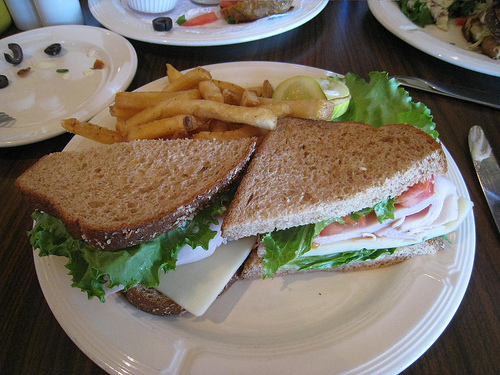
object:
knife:
[468, 123, 499, 232]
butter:
[468, 125, 488, 163]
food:
[14, 63, 475, 318]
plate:
[31, 61, 478, 374]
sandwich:
[219, 117, 474, 283]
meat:
[302, 175, 463, 247]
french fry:
[60, 118, 127, 142]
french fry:
[127, 115, 198, 141]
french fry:
[161, 97, 278, 132]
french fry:
[163, 66, 212, 91]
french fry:
[260, 97, 336, 122]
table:
[1, 1, 499, 373]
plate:
[0, 24, 137, 149]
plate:
[87, 1, 327, 46]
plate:
[365, 0, 497, 76]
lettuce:
[27, 169, 244, 302]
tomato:
[321, 180, 435, 234]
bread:
[14, 136, 256, 253]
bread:
[122, 265, 243, 316]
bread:
[218, 115, 448, 244]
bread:
[238, 226, 456, 280]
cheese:
[154, 233, 257, 316]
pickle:
[273, 76, 353, 122]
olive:
[152, 16, 174, 32]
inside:
[253, 175, 475, 279]